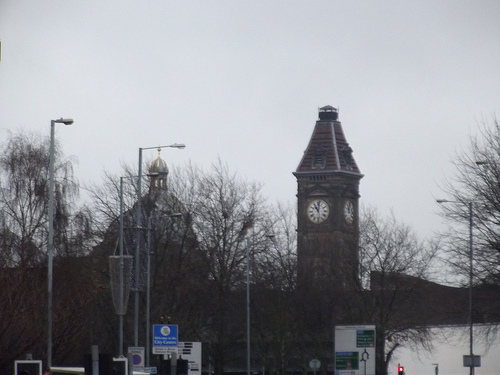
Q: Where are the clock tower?
A: Near the trees.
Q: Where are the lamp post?
A: By the trees.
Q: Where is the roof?
A: On the building.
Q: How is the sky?
A: Cloudy above the clock tower.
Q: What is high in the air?
A: Light post.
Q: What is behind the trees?
A: Stone tower.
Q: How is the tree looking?
A: No leaves.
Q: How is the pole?
A: Tall and grey.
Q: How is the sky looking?
A: Grey and cloudy.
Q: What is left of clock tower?
A: Tall and bare trees.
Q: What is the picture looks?
A: Picture of city.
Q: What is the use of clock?
A: To know the time.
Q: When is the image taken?
A: When trees do not have leaves.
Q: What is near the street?
A: A light pole.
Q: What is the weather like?
A: Cloudy and overcast.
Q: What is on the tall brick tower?
A: A clock.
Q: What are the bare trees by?
A: The road.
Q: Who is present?
A: No one.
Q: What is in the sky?
A: Nothing.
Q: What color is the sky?
A: Gray.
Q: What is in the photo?
A: Tower.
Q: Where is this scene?
A: In a city.